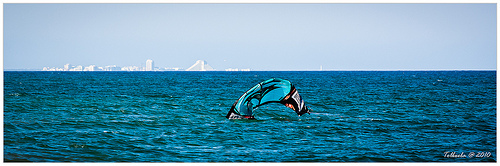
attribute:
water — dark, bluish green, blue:
[4, 80, 493, 163]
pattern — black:
[240, 77, 279, 105]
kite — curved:
[223, 73, 310, 123]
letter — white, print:
[442, 150, 467, 160]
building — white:
[49, 49, 269, 99]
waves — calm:
[337, 82, 476, 140]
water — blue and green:
[8, 60, 498, 157]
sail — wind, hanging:
[220, 72, 315, 129]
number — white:
[471, 147, 484, 157]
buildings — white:
[41, 57, 251, 72]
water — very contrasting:
[12, 72, 489, 154]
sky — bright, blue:
[1, 0, 495, 71]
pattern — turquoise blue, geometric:
[233, 74, 302, 119]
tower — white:
[144, 56, 154, 70]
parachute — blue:
[219, 73, 312, 130]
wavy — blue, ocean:
[149, 94, 207, 122]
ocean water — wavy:
[5, 62, 489, 157]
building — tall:
[144, 52, 154, 68]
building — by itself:
[141, 63, 159, 70]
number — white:
[469, 148, 485, 157]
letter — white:
[446, 147, 458, 160]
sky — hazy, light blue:
[297, 17, 449, 77]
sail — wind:
[232, 83, 306, 120]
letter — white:
[455, 148, 461, 157]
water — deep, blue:
[36, 54, 482, 150]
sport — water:
[220, 72, 315, 138]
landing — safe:
[202, 109, 347, 149]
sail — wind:
[230, 70, 314, 124]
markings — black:
[255, 81, 273, 102]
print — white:
[284, 87, 308, 111]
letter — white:
[284, 86, 322, 123]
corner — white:
[228, 112, 241, 118]